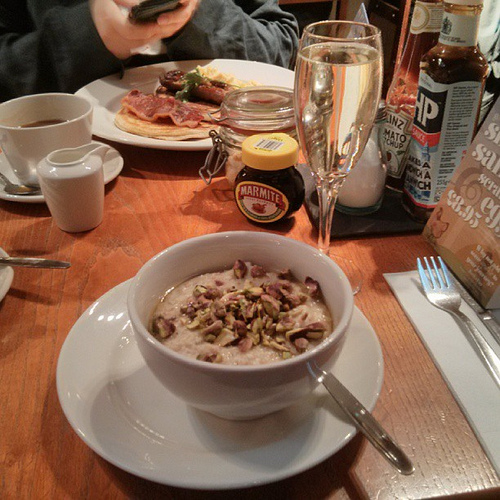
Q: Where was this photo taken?
A: In a restaurant.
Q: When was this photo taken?
A: Before a meal.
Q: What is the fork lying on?
A: A napkin.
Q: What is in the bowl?
A: Soup.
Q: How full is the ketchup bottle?
A: Half full.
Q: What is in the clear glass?
A: Wine.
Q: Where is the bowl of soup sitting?
A: Table.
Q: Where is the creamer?
A: On the table.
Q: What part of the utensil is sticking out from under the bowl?
A: The handle.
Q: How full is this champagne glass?
A: Completely full.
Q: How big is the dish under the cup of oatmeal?
A: Medium sized.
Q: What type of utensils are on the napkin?
A: A fork and knife.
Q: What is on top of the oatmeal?
A: Crunchy toppings.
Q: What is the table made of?
A: Wood.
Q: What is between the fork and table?
A: A napkin.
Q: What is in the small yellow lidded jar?
A: Marmite.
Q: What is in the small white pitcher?
A: Cream.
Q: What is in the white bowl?
A: Oatmeal.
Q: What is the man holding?
A: Phone.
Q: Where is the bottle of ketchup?
A: On the right side.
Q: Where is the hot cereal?
A: In the white bowl.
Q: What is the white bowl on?
A: White plate.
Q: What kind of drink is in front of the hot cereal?
A: White wine.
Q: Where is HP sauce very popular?
A: In England.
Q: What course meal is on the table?
A: Breakfast.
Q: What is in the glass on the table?
A: Wine.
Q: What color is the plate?
A: White.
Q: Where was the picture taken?
A: At a restaurant.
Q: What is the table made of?
A: Wood.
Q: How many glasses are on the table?
A: One.